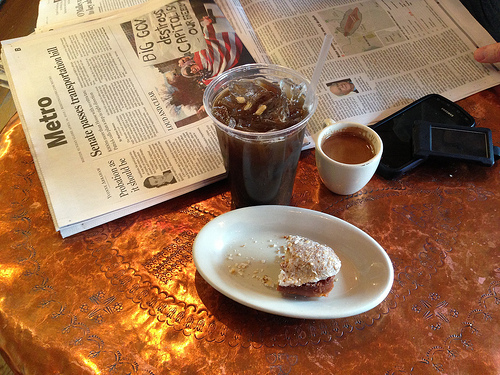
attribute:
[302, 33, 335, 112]
straw — clear, white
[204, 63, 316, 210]
cup — clear, plastic, small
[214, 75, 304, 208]
soda — coca-cola, iced, black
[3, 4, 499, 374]
table — gold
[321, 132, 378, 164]
coffe — hot, espresso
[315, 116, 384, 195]
cup — small, white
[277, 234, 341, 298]
muffin — half-eaten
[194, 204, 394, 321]
plate — white, oval, small, round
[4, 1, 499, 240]
newspaper — open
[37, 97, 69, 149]
metro — big, black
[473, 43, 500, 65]
fingernail — pink, female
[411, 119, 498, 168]
case — black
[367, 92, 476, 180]
cellphone — black, small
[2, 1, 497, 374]
table cloth — red, gold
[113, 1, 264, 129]
picture — colored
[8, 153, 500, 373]
design — engraved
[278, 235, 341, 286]
top — white